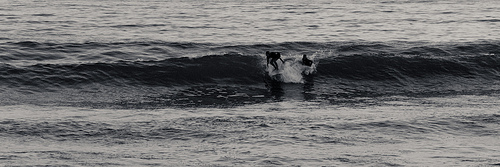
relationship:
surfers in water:
[264, 49, 316, 77] [1, 1, 500, 165]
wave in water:
[63, 55, 500, 86] [1, 1, 500, 165]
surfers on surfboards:
[264, 49, 316, 77] [269, 68, 317, 79]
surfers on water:
[264, 49, 316, 77] [1, 1, 500, 165]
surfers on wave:
[264, 49, 316, 77] [63, 55, 500, 86]